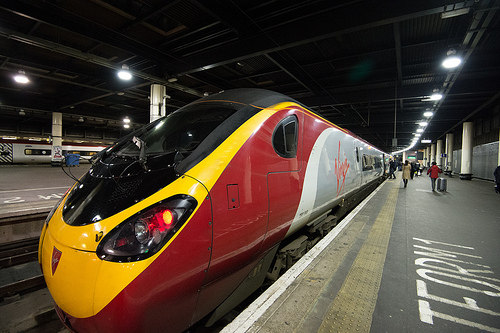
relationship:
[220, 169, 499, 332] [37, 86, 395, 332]
platform next to train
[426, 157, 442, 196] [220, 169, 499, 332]
person on platform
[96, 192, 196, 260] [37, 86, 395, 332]
headlight on train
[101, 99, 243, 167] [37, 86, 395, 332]
windshield on train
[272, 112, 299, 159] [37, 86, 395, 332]
side window of train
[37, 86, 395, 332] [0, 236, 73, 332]
train on tracks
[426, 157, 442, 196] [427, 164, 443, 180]
person in jacket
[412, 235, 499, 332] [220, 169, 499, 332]
writing on platform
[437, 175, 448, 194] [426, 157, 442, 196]
luggage bag beside person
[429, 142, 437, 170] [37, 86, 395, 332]
pillar near train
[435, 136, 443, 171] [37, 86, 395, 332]
pillar near train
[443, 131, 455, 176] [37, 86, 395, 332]
pillar near train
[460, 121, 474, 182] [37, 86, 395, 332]
pillar near train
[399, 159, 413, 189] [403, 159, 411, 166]
person with hair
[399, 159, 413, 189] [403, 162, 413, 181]
person in coat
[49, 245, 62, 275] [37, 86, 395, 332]
logo on train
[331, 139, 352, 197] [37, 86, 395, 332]
writing on side of train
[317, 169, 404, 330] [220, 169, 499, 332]
line on platform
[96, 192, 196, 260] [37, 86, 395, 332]
headlight on front of train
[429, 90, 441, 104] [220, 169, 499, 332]
light above platform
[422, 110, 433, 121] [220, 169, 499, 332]
light above platform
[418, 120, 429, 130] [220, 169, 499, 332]
light above platform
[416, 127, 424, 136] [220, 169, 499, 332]
light above platform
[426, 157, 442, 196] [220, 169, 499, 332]
person walking on platform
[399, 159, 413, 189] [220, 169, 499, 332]
person walking on platform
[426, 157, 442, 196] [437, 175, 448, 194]
person with luggage bag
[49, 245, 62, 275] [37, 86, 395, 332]
logo on front of train